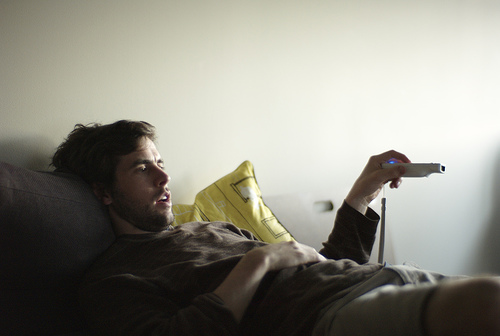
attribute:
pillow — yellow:
[217, 167, 283, 227]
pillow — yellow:
[231, 186, 275, 216]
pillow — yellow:
[221, 176, 261, 215]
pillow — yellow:
[218, 181, 262, 217]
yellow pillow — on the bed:
[169, 160, 302, 242]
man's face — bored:
[116, 133, 172, 230]